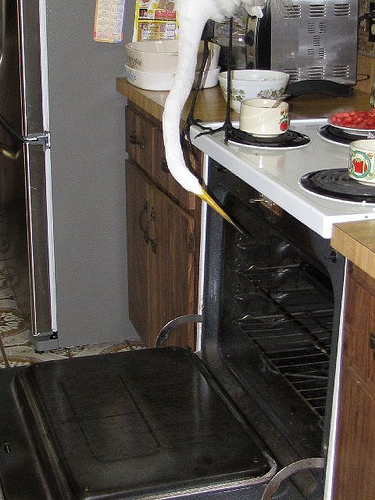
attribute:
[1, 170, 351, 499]
oven door — open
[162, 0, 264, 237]
bird — white, looking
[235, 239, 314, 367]
racks — black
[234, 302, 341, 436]
grate — metal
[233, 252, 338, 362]
grate — metal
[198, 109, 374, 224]
stove top — metal, gas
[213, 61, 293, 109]
bowl — sitting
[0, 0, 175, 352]
refrigerator — grey, black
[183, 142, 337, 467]
oven — open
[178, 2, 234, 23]
feather — white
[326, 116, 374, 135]
plate — white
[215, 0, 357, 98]
oven — toaster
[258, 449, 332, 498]
hinge — metal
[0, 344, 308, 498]
oven door — black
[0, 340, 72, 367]
tile — designed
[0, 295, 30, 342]
tile — designed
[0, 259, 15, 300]
tile — designed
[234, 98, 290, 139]
cup — white, floral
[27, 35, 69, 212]
fridge — silver